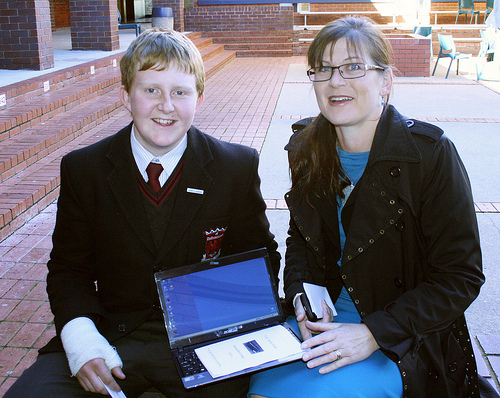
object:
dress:
[246, 142, 405, 398]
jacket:
[279, 103, 487, 398]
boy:
[0, 27, 281, 398]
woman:
[247, 16, 485, 398]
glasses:
[305, 62, 385, 83]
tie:
[144, 162, 164, 195]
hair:
[115, 23, 209, 98]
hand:
[59, 317, 126, 397]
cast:
[58, 315, 124, 377]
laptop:
[150, 245, 315, 391]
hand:
[296, 318, 381, 377]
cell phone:
[300, 293, 324, 324]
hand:
[288, 294, 336, 343]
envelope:
[301, 281, 338, 319]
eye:
[318, 65, 334, 73]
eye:
[346, 64, 361, 71]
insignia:
[201, 224, 230, 264]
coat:
[35, 119, 283, 353]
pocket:
[186, 214, 234, 267]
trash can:
[150, 7, 175, 31]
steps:
[0, 29, 238, 240]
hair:
[288, 13, 395, 211]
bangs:
[306, 29, 373, 64]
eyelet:
[389, 199, 395, 204]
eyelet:
[379, 229, 385, 235]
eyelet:
[346, 254, 354, 262]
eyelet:
[347, 287, 354, 293]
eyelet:
[400, 370, 408, 378]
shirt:
[127, 122, 190, 195]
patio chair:
[429, 33, 480, 83]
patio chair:
[455, 0, 481, 26]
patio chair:
[484, 0, 492, 17]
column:
[0, 0, 55, 69]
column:
[69, 0, 120, 51]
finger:
[90, 357, 122, 393]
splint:
[97, 373, 130, 398]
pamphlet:
[188, 321, 309, 382]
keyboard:
[169, 316, 312, 380]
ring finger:
[334, 349, 343, 360]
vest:
[130, 142, 188, 253]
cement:
[282, 55, 477, 84]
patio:
[0, 0, 500, 398]